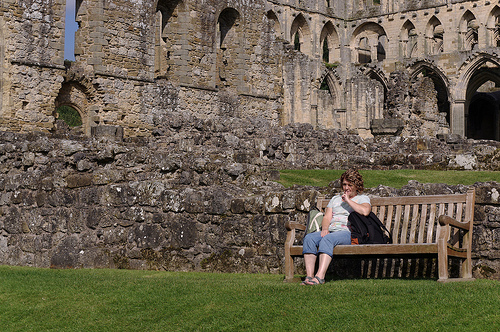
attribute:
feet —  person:
[296, 272, 325, 293]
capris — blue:
[298, 225, 355, 259]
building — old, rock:
[33, 6, 496, 141]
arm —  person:
[348, 202, 373, 216]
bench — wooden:
[280, 181, 474, 283]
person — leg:
[306, 155, 348, 245]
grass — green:
[1, 167, 498, 329]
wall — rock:
[9, 112, 480, 277]